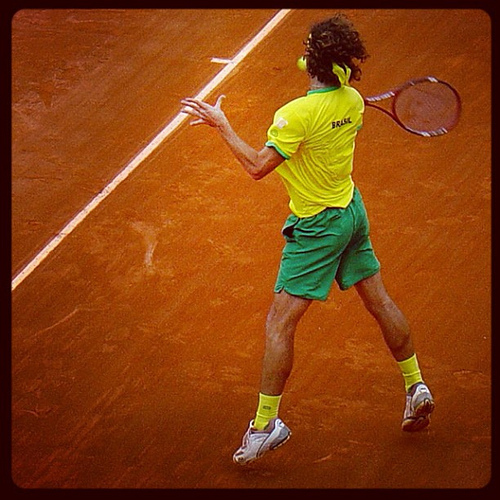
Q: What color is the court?
A: Brown.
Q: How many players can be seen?
A: 1.